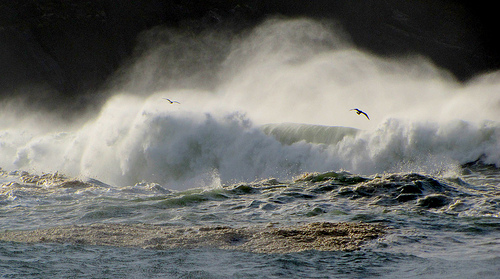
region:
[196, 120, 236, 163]
part of a splash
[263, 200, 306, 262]
part of a ground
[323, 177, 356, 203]
part of a water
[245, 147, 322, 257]
part of a splash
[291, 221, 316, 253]
part of a ground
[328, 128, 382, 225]
par of a palh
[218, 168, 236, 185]
edge of a watrer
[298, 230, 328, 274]
part of a ground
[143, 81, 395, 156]
the birds are flying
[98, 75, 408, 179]
white splash of water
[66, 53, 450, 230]
white splash of water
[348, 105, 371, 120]
a seagull flying over crashing waves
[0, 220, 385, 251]
rocks forming a jetty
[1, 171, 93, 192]
rough water landing on the jetty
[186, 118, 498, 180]
waves crest breaking onto rocks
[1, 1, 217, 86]
dark sky above the waves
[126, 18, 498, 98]
mist forming from crashing waves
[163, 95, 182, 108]
a seagull flying into the mist of a wave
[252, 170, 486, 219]
churning water from the shallow rocks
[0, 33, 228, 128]
mist from the waves crashing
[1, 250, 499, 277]
calm waters in the foreground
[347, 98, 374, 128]
Bird flying over water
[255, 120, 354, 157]
Rolling top of a wave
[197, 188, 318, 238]
Waves in a large body of water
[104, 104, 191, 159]
White crest of a wave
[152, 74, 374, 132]
Two birds flying in the air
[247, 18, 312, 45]
Spray from a large wave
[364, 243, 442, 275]
White water on top of a sea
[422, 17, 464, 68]
Dark background behind a wave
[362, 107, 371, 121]
Wing of a bird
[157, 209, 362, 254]
Light reflecting off of water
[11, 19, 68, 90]
white clouds in blue sky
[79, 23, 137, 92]
white clouds in blue sky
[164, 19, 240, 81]
white clouds in blue sky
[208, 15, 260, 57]
white clouds in blue sky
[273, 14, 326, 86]
white clouds in blue sky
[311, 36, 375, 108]
white clouds in blue sky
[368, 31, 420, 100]
white clouds in blue sky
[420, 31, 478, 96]
white clouds in blue sky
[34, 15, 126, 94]
white clouds in blue sky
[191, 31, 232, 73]
white clouds in blue sky